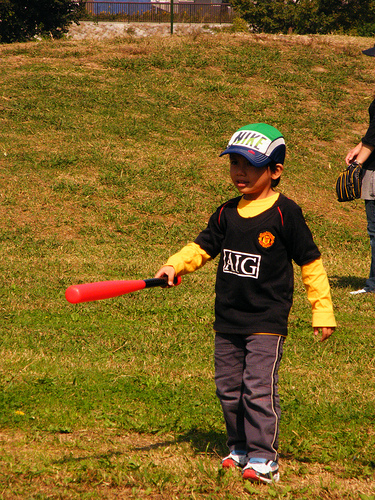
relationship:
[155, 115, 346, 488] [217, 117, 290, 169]
boy wearing hat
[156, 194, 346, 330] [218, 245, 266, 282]
shirt has letters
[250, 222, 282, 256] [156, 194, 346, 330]
label on shirt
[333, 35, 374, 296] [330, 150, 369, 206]
person holding mit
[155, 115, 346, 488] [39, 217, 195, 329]
boy playing baseball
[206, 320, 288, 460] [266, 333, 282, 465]
pants have line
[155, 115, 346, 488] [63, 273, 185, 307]
boy holding bat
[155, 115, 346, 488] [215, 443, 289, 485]
boy wearing shoes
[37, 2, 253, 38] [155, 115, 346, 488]
fence above boy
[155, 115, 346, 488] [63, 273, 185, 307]
boy has bat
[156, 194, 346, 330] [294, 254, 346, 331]
shirt has long sleeves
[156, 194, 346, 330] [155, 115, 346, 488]
shirt on boy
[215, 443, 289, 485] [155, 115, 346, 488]
shoes on boy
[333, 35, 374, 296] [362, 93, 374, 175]
person wearing jacket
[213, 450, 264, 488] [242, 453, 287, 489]
tip of shoe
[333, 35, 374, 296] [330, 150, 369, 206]
person has mit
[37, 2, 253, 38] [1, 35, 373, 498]
fence above lawn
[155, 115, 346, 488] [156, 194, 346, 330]
boy wearing shirt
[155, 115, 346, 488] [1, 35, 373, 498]
boy on lawn